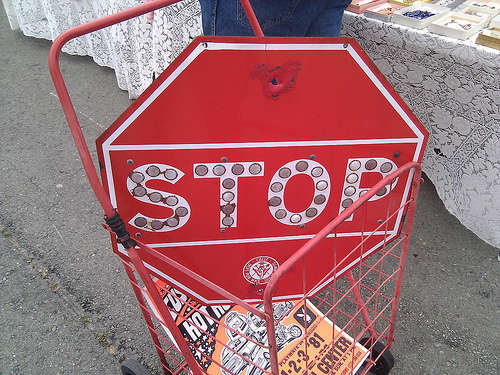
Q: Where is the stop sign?
A: In a cart.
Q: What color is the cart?
A: Red.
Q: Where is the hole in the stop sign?
A: Near the top.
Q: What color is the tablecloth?
A: White.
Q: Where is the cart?
A: On the ground.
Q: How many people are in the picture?
A: 1.